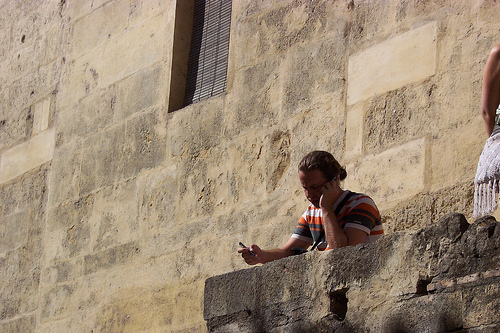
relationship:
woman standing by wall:
[479, 35, 499, 128] [352, 97, 456, 161]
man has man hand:
[237, 149, 385, 267] [234, 239, 266, 266]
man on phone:
[237, 149, 385, 267] [325, 171, 337, 186]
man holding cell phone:
[237, 95, 418, 315] [323, 169, 341, 189]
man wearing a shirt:
[237, 149, 385, 267] [288, 188, 380, 250]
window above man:
[176, 7, 227, 99] [239, 142, 367, 259]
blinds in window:
[185, 0, 231, 105] [176, 7, 227, 99]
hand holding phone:
[315, 176, 342, 211] [231, 236, 254, 256]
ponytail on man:
[342, 162, 348, 180] [237, 149, 385, 267]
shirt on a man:
[292, 186, 385, 249] [233, 146, 380, 270]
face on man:
[300, 169, 325, 206] [237, 149, 385, 267]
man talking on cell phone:
[237, 149, 385, 267] [320, 169, 341, 189]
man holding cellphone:
[237, 149, 385, 267] [325, 173, 345, 187]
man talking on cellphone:
[237, 149, 385, 267] [320, 175, 337, 191]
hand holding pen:
[238, 242, 265, 265] [234, 239, 259, 262]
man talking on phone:
[237, 149, 385, 267] [236, 242, 258, 260]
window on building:
[176, 7, 227, 99] [1, 2, 499, 332]